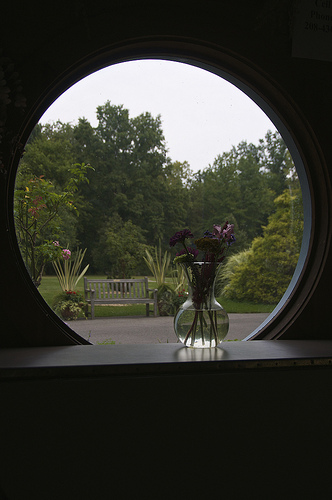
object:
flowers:
[194, 236, 222, 251]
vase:
[172, 260, 229, 351]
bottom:
[172, 299, 230, 349]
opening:
[179, 260, 224, 267]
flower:
[212, 220, 235, 245]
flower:
[169, 227, 195, 247]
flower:
[172, 252, 195, 265]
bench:
[83, 275, 159, 320]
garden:
[12, 169, 307, 319]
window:
[7, 35, 332, 349]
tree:
[12, 157, 95, 281]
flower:
[61, 248, 72, 261]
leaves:
[26, 195, 27, 198]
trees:
[127, 175, 132, 202]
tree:
[93, 209, 157, 290]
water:
[173, 307, 229, 348]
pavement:
[62, 312, 270, 345]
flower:
[175, 246, 199, 259]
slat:
[129, 283, 132, 297]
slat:
[98, 283, 101, 299]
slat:
[102, 282, 105, 298]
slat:
[107, 283, 110, 299]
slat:
[141, 282, 144, 297]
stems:
[184, 314, 197, 344]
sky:
[37, 59, 299, 180]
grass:
[38, 274, 278, 320]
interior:
[0, 1, 332, 498]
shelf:
[0, 340, 332, 380]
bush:
[215, 185, 303, 307]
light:
[179, 335, 224, 349]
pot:
[60, 300, 79, 320]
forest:
[14, 96, 305, 321]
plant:
[48, 241, 91, 319]